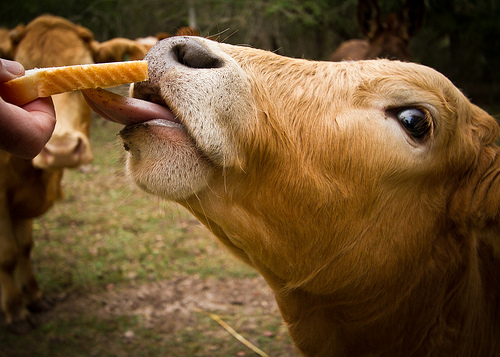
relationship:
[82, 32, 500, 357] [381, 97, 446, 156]
animal has eye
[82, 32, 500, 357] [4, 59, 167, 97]
animal licking bread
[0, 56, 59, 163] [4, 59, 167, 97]
hand holding bread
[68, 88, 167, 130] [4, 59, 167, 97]
tongue licking bread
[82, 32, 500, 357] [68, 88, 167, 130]
animal has tongue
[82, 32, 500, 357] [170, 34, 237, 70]
animal has nostril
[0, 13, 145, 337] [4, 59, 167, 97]
animal behind bread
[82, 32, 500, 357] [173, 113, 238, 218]
animal has whiskers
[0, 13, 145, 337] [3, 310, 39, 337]
animal has hoof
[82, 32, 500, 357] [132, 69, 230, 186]
animal has mouth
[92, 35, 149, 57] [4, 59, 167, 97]
ear behind bread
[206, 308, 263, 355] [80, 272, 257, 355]
straw on ground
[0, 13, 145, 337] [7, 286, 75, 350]
animal has hooves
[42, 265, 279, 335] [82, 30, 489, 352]
dirt by cow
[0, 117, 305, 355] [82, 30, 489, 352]
grass by cow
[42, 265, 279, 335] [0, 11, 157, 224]
dirt by cow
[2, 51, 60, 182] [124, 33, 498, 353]
hand in cow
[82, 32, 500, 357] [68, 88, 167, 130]
animal with tongue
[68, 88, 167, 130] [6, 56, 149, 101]
tongue licking bread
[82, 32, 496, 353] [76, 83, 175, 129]
animal with tongue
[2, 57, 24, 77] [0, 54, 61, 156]
fingernail on hand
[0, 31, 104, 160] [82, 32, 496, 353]
person feeding animal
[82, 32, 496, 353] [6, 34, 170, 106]
animal eating bread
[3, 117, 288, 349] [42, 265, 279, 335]
grass with dirt